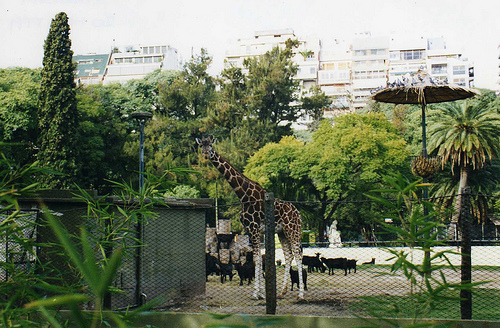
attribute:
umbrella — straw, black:
[371, 67, 476, 106]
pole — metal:
[417, 102, 429, 269]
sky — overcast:
[93, 6, 492, 76]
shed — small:
[3, 189, 213, 306]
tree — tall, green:
[31, 36, 104, 181]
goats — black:
[207, 246, 258, 295]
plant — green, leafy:
[380, 194, 452, 305]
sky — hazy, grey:
[0, 0, 494, 93]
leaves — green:
[33, 11, 88, 190]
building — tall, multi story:
[108, 41, 180, 90]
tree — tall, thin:
[27, 12, 81, 202]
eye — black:
[197, 142, 204, 149]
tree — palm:
[405, 90, 499, 320]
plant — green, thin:
[369, 168, 483, 326]